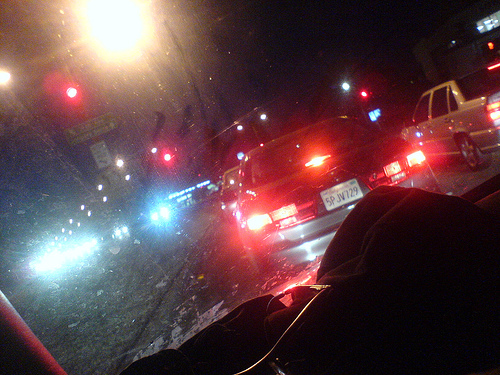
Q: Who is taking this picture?
A: Person in a car.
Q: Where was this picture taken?
A: A street.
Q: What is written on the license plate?
A: 5PJV729.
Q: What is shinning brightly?
A: Lights.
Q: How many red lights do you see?
A: 6.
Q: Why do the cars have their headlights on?
A: It is night.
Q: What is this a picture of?
A: Traffic.